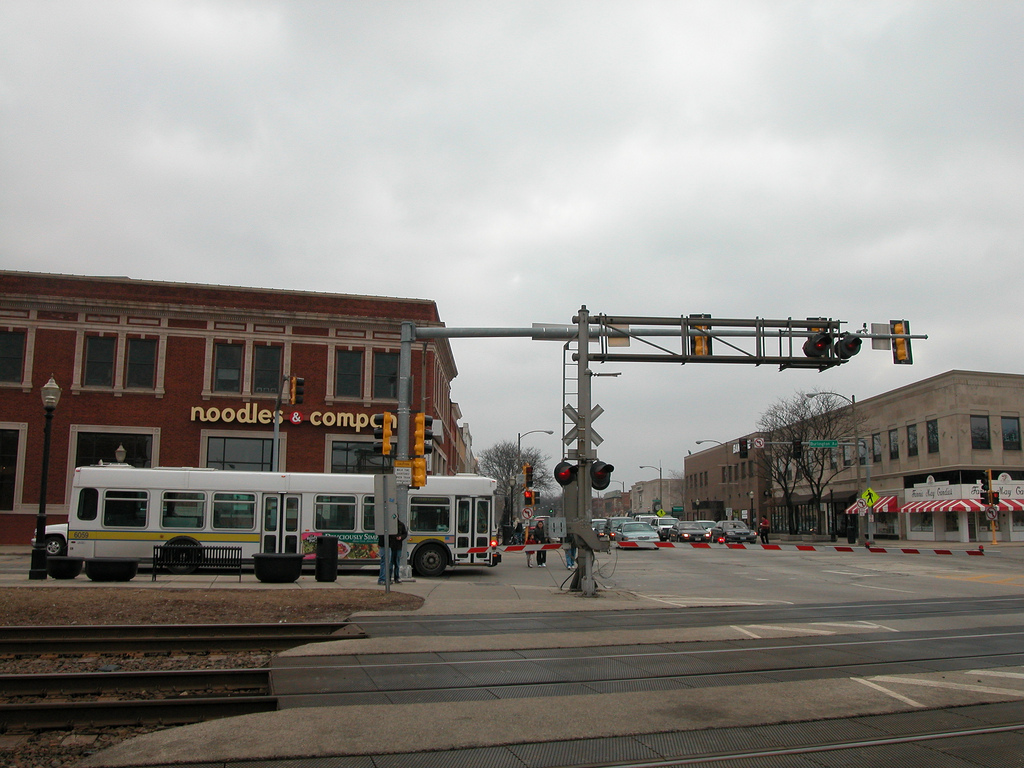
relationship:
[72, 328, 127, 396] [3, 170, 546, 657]
window on building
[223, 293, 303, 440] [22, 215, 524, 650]
window on building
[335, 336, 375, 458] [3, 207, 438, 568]
window on building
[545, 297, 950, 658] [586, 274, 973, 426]
structure for signs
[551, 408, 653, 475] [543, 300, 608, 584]
sign on pole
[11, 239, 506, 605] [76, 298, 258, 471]
building made of bricks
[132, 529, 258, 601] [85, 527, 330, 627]
bench on sidewalk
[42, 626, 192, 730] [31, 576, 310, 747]
tracks on ground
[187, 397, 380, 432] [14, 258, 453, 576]
lettering on building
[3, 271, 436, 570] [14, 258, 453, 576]
wall on building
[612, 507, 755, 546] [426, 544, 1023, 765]
cars on street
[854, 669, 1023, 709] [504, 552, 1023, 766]
lines painted on road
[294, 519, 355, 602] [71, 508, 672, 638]
trash can on street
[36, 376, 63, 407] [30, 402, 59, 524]
light on pole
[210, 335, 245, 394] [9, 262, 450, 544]
window adorning building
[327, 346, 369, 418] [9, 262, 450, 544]
window on a building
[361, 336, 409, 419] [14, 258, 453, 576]
window on a building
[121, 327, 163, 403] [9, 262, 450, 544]
window on a building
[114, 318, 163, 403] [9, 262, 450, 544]
window on a building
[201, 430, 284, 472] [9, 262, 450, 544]
window on a building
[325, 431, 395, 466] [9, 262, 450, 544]
window on a building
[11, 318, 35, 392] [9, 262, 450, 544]
window on a building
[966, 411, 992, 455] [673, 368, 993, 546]
window on a building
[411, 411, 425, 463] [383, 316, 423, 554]
traffic light on pole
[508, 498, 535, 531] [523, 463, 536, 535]
sign on pole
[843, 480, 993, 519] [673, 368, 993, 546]
awning on building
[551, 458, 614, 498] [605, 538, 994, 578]
lights for crossing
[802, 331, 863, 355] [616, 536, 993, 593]
lights for crossing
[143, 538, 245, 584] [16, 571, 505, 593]
bench on sidewalk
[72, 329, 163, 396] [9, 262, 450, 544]
window on building